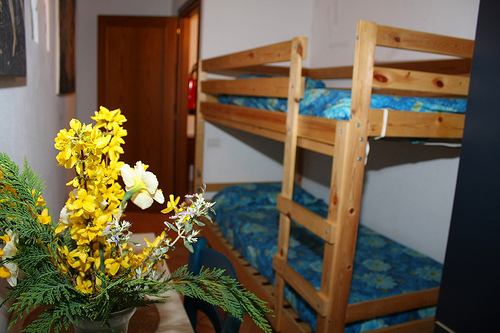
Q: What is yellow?
A: Flowers.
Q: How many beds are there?
A: Two.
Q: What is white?
A: Walls.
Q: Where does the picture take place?
A: In a bedroom.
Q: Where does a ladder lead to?
A: To the top bed.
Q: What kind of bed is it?
A: Bunk bed.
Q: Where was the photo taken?
A: In a bedroom.